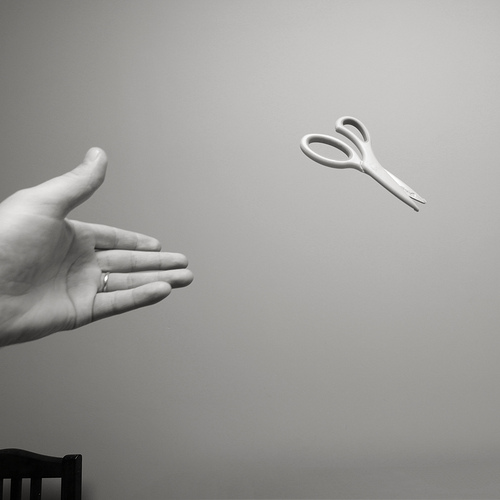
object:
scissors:
[298, 115, 428, 213]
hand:
[0, 145, 196, 349]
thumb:
[1, 146, 110, 219]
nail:
[84, 146, 103, 164]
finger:
[93, 223, 161, 252]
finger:
[94, 248, 189, 273]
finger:
[98, 268, 196, 292]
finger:
[92, 280, 172, 321]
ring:
[102, 271, 111, 292]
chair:
[0, 446, 83, 499]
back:
[0, 448, 81, 500]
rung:
[29, 475, 45, 499]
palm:
[0, 212, 101, 347]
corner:
[426, 422, 499, 500]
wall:
[0, 0, 497, 499]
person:
[0, 145, 195, 349]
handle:
[299, 132, 362, 169]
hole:
[308, 140, 350, 162]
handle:
[334, 115, 372, 151]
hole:
[343, 123, 367, 142]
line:
[62, 252, 86, 330]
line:
[90, 291, 99, 324]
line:
[54, 228, 76, 280]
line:
[1, 286, 39, 302]